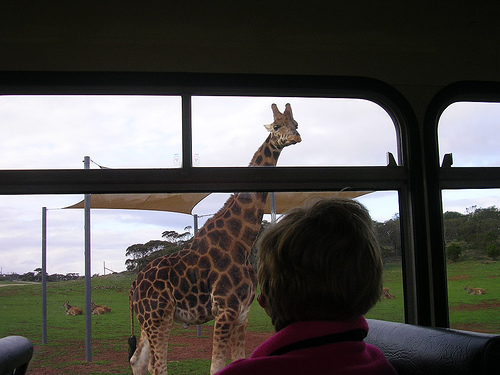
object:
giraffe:
[123, 99, 303, 374]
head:
[261, 99, 305, 148]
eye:
[272, 124, 280, 132]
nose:
[292, 131, 300, 136]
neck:
[182, 133, 287, 256]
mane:
[211, 193, 237, 216]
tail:
[125, 291, 139, 361]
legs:
[141, 315, 167, 375]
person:
[213, 194, 396, 375]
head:
[251, 192, 385, 331]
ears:
[280, 103, 294, 116]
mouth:
[292, 140, 302, 144]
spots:
[174, 260, 187, 276]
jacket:
[204, 320, 402, 375]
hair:
[261, 198, 385, 329]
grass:
[0, 260, 500, 375]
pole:
[40, 205, 50, 347]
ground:
[0, 261, 500, 375]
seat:
[361, 315, 498, 374]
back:
[290, 249, 344, 304]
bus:
[0, 0, 500, 375]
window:
[0, 96, 184, 170]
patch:
[54, 344, 83, 359]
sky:
[0, 95, 500, 284]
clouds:
[0, 95, 500, 276]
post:
[81, 155, 94, 355]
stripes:
[152, 339, 158, 345]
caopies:
[88, 198, 205, 216]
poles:
[38, 205, 51, 343]